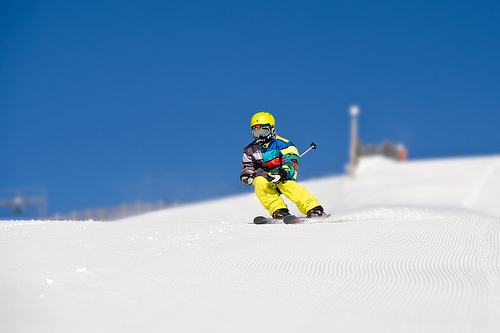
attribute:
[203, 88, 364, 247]
skier — skiing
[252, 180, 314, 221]
pants — yellow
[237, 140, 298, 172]
jacket — colorful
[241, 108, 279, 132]
helmet — yellow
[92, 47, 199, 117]
sky — clear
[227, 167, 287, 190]
gloves — white